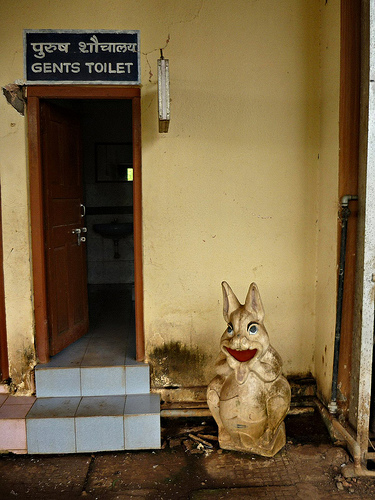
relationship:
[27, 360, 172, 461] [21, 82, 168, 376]
stairs lead to door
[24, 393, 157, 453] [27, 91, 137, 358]
step by door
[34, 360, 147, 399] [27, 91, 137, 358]
step by door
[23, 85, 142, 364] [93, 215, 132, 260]
bathroom has sink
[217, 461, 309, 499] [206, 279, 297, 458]
floor in front of figurine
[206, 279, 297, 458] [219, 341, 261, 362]
figurine holds mouth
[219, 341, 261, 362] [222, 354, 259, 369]
mouth held with hands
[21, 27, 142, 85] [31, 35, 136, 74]
black sign has white letters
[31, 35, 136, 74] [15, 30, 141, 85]
white letters have white trim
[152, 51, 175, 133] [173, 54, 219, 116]
light hangs on wall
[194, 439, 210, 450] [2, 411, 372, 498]
trash on floor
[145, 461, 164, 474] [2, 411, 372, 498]
trash on floor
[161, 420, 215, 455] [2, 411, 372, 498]
trash on floor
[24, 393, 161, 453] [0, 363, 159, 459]
step covered tiles